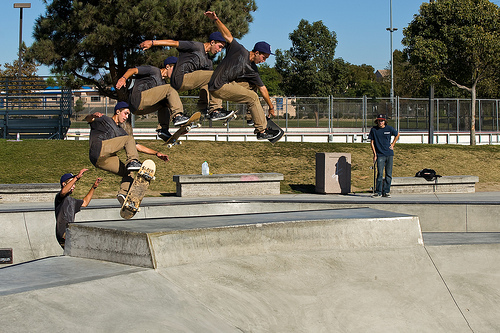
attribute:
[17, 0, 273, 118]
trees — tall, bushy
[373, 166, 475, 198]
bench — concrete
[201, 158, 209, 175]
container — large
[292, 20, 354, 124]
tree — green